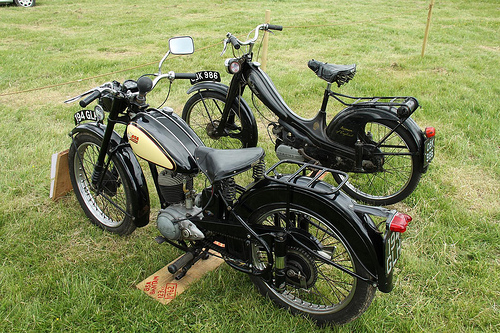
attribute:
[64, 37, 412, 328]
bike — black, parked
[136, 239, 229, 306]
cardboard — big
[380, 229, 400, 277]
plate — black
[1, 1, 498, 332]
grass — green